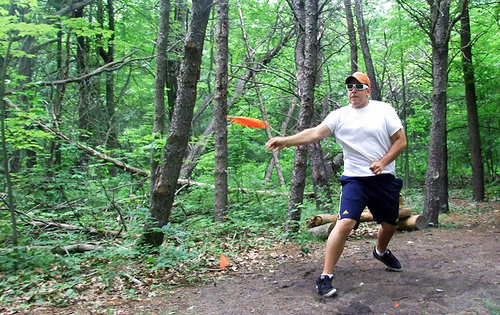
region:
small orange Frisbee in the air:
[211, 105, 277, 135]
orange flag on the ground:
[217, 251, 247, 270]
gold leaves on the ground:
[86, 249, 251, 282]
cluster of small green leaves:
[33, 226, 158, 298]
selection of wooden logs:
[305, 196, 459, 237]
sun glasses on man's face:
[335, 74, 379, 96]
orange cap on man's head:
[328, 61, 387, 93]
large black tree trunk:
[78, 61, 234, 313]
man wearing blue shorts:
[324, 154, 478, 238]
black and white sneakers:
[307, 258, 375, 302]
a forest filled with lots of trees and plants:
[1, 1, 231, 264]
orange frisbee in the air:
[230, 116, 270, 128]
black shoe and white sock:
[317, 272, 334, 298]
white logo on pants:
[341, 208, 349, 214]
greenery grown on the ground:
[484, 295, 499, 313]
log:
[306, 224, 329, 238]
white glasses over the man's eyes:
[344, 82, 369, 90]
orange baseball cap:
[345, 72, 372, 82]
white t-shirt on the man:
[342, 101, 397, 176]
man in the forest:
[266, 0, 406, 314]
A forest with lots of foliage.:
[12, 7, 247, 307]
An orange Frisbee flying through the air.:
[208, 90, 275, 137]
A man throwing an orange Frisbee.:
[202, 33, 452, 303]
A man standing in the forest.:
[261, 30, 456, 303]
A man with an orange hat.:
[266, 54, 452, 306]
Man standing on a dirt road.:
[265, 56, 467, 310]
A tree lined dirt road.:
[54, 5, 477, 293]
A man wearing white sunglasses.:
[305, 64, 414, 306]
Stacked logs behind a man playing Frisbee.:
[282, 178, 445, 258]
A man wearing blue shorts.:
[305, 65, 443, 285]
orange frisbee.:
[210, 94, 281, 140]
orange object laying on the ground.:
[204, 239, 254, 276]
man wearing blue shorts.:
[298, 166, 412, 238]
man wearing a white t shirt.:
[300, 109, 428, 184]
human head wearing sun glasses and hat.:
[338, 59, 393, 125]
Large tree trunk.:
[115, 0, 223, 258]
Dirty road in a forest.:
[0, 201, 485, 310]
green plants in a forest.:
[30, 99, 126, 241]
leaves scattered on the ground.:
[124, 259, 196, 300]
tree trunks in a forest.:
[186, 22, 237, 109]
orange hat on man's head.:
[347, 71, 372, 84]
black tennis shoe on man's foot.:
[315, 276, 349, 296]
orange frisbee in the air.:
[223, 107, 264, 131]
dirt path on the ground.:
[237, 282, 294, 303]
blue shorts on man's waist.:
[342, 183, 399, 203]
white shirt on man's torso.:
[338, 113, 375, 152]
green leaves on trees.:
[22, 125, 78, 188]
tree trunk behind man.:
[427, 85, 454, 194]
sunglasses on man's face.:
[344, 83, 369, 93]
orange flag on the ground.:
[203, 253, 234, 279]